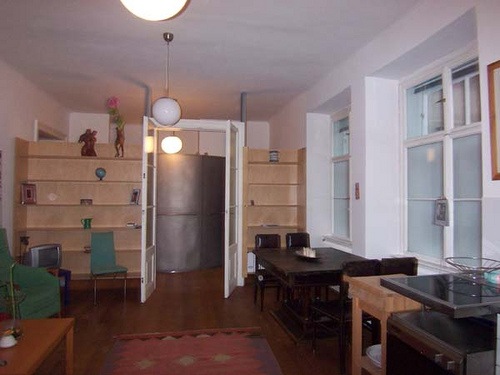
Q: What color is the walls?
A: White.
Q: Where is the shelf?
A: On the back wall.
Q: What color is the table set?
A: Brown.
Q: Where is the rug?
A: On the floor.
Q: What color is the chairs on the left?
A: Green.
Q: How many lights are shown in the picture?
A: One.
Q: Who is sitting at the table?
A: No one.